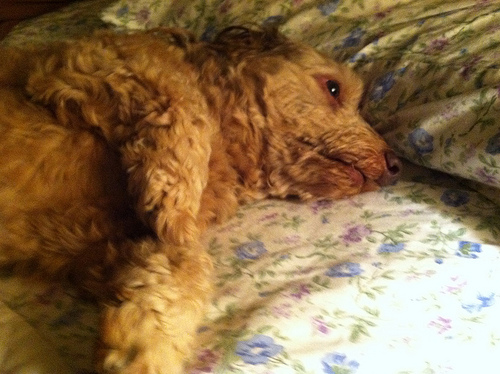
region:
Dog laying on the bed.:
[9, 25, 401, 372]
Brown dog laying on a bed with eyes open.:
[12, 11, 453, 372]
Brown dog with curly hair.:
[1, 27, 404, 370]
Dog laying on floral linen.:
[2, 1, 499, 372]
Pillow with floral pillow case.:
[104, 1, 499, 190]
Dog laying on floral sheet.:
[5, 19, 411, 371]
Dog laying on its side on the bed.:
[3, 29, 471, 366]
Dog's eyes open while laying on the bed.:
[222, 21, 404, 203]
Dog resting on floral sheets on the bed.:
[2, 2, 497, 372]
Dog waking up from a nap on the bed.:
[4, 12, 496, 370]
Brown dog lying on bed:
[7, 5, 404, 367]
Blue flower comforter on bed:
[241, 198, 446, 353]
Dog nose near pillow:
[334, 114, 411, 194]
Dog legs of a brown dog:
[12, 29, 226, 372]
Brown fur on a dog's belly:
[7, 108, 132, 261]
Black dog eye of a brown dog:
[321, 63, 355, 105]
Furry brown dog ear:
[194, 30, 264, 125]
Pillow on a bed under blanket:
[360, 3, 499, 181]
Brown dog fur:
[80, 41, 193, 137]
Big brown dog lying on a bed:
[10, 14, 443, 348]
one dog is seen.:
[12, 48, 384, 350]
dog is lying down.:
[13, 51, 378, 321]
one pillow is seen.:
[380, 26, 477, 126]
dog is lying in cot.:
[70, 42, 367, 277]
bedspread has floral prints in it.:
[259, 240, 420, 346]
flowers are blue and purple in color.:
[340, 220, 400, 282]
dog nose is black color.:
[374, 151, 404, 187]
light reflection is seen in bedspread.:
[250, 233, 480, 372]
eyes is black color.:
[325, 75, 341, 101]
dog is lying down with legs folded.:
[22, 24, 482, 351]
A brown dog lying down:
[0, 18, 398, 372]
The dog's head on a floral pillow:
[106, 0, 498, 187]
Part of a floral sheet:
[206, 195, 496, 370]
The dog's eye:
[302, 63, 352, 114]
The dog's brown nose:
[373, 144, 406, 189]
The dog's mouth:
[290, 125, 382, 196]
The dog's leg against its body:
[28, 38, 211, 241]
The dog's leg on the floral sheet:
[100, 234, 238, 371]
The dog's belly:
[1, 109, 104, 265]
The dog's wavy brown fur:
[49, 53, 165, 136]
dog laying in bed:
[23, 26, 438, 253]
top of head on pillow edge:
[205, 6, 405, 211]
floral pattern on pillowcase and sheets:
[387, 10, 482, 285]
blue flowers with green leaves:
[305, 231, 420, 331]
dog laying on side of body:
[70, 16, 426, 261]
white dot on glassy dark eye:
[295, 35, 355, 111]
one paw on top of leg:
[40, 60, 240, 305]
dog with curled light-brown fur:
[30, 65, 265, 180]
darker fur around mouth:
[255, 55, 380, 206]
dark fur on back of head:
[200, 16, 296, 76]